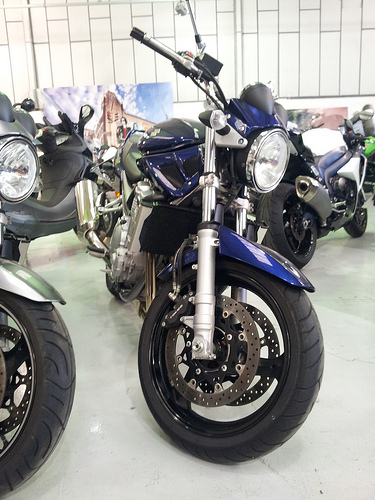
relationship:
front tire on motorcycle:
[138, 256, 326, 462] [67, 22, 342, 473]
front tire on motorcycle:
[0, 289, 78, 497] [1, 93, 88, 499]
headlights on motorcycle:
[253, 126, 289, 195] [67, 22, 342, 473]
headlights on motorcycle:
[0, 140, 39, 203] [1, 93, 88, 499]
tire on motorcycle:
[138, 256, 326, 462] [67, 22, 342, 473]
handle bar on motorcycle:
[127, 0, 231, 116] [67, 22, 342, 473]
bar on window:
[20, 0, 43, 88] [1, 3, 374, 100]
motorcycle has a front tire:
[1, 93, 88, 499] [0, 289, 78, 497]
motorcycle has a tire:
[67, 22, 342, 473] [138, 256, 326, 462]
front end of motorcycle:
[130, 2, 325, 465] [67, 22, 342, 473]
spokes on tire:
[179, 294, 284, 388] [138, 256, 326, 462]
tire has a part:
[138, 256, 326, 462] [218, 264, 326, 465]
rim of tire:
[148, 272, 289, 437] [138, 256, 326, 462]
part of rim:
[223, 270, 290, 436] [148, 272, 289, 437]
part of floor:
[176, 203, 374, 499] [3, 191, 370, 498]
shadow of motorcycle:
[105, 294, 179, 451] [67, 22, 342, 473]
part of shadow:
[125, 349, 168, 438] [105, 294, 179, 451]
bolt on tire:
[224, 331, 234, 341] [138, 256, 326, 462]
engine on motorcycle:
[103, 218, 146, 297] [67, 22, 342, 473]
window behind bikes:
[1, 3, 374, 100] [1, 0, 374, 499]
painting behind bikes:
[30, 80, 179, 160] [1, 0, 374, 499]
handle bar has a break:
[127, 0, 231, 116] [144, 32, 201, 74]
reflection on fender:
[229, 231, 270, 266] [218, 223, 314, 295]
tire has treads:
[138, 256, 326, 462] [182, 284, 324, 464]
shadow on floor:
[105, 294, 179, 451] [3, 191, 370, 498]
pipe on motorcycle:
[75, 177, 109, 254] [67, 22, 342, 473]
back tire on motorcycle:
[344, 203, 369, 237] [304, 125, 374, 237]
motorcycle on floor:
[67, 22, 342, 473] [3, 191, 370, 498]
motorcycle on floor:
[1, 93, 88, 499] [3, 191, 370, 498]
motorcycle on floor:
[304, 125, 374, 237] [3, 191, 370, 498]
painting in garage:
[30, 80, 179, 160] [1, 0, 372, 495]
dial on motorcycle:
[201, 52, 224, 75] [67, 22, 342, 473]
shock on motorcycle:
[143, 256, 157, 309] [67, 22, 342, 473]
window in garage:
[1, 3, 374, 100] [1, 0, 372, 495]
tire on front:
[138, 256, 326, 462] [138, 28, 326, 472]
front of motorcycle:
[138, 28, 326, 472] [67, 22, 342, 473]